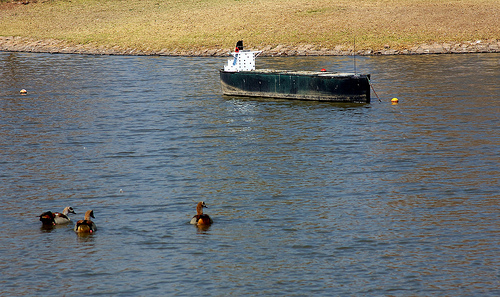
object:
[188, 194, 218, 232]
duck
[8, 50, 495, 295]
lake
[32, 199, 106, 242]
ducks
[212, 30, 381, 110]
boat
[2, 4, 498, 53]
hill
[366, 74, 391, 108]
string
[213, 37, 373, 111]
boat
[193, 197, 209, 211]
head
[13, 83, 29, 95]
item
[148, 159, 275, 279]
water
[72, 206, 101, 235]
mallar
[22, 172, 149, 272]
water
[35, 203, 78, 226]
duck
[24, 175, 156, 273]
water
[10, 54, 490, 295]
water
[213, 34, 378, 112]
tanker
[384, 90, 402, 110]
buoy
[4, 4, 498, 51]
area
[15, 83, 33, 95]
buoy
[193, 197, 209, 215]
head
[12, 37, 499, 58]
border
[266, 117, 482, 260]
water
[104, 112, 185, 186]
water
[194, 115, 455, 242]
water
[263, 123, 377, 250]
water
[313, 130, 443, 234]
water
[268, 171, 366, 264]
water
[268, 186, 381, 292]
water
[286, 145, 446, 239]
water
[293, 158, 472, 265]
water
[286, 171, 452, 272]
water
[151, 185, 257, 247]
duck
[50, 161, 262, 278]
ducks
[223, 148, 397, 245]
water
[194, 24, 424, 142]
boat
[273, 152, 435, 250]
water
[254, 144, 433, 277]
water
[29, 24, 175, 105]
shore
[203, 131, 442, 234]
water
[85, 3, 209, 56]
grass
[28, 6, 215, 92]
beach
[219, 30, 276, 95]
cover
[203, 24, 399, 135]
boat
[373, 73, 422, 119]
flatation device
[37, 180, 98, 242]
duck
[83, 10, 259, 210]
food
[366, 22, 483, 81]
rocks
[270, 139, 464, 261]
water